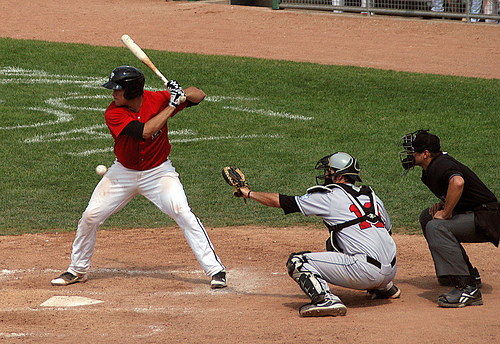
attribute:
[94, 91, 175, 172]
shirt — red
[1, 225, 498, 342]
infield clay — red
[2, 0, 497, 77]
infield clay — red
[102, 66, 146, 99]
helmet — black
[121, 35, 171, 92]
baseball bat — wooden ,  regulation size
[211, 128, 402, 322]
catcher — crouching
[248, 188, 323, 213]
arm — outstretched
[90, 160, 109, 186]
baseball — small, white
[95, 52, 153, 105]
helmet — black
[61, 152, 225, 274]
trouser — white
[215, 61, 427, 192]
grass — white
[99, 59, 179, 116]
helmet — black